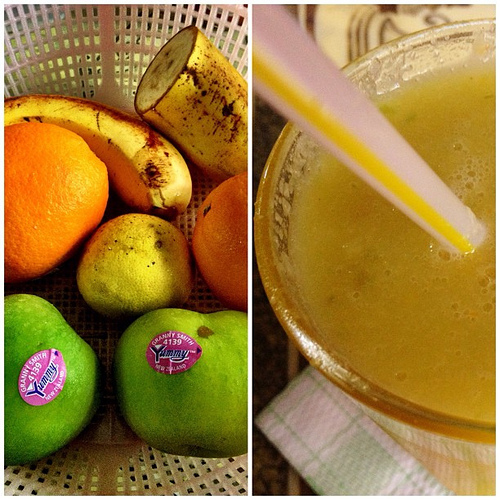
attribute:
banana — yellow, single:
[36, 96, 200, 190]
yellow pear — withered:
[73, 212, 192, 321]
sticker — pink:
[147, 333, 202, 370]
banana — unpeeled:
[1, 87, 190, 215]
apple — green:
[109, 307, 246, 448]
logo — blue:
[151, 343, 191, 360]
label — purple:
[146, 330, 201, 372]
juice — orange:
[404, 147, 497, 316]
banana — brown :
[133, 26, 254, 181]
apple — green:
[108, 300, 252, 458]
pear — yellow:
[73, 211, 197, 316]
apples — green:
[5, 279, 250, 470]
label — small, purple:
[148, 329, 213, 376]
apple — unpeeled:
[8, 294, 103, 461]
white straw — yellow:
[260, 40, 487, 244]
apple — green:
[117, 303, 246, 455]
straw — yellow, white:
[256, 7, 489, 259]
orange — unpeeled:
[14, 127, 139, 245]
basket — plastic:
[16, 12, 264, 494]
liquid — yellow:
[273, 7, 496, 446]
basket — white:
[4, 449, 246, 499]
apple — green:
[44, 240, 279, 442]